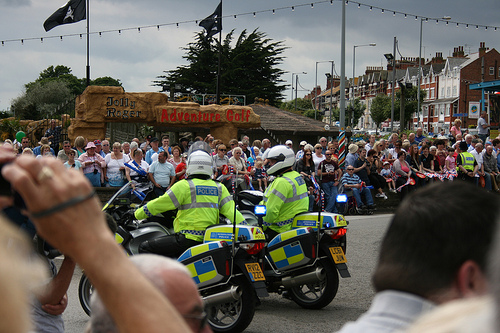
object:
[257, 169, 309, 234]
jacket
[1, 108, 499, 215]
spectators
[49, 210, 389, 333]
street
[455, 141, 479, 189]
man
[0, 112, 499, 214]
crowd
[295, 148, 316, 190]
woman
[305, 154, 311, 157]
sunglasses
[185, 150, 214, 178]
helmet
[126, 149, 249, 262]
man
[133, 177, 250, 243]
coat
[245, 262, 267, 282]
license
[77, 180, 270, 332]
bike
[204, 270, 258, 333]
wheel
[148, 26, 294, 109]
pines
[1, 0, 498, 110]
sky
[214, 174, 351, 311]
bikes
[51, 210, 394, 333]
concrete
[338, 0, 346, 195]
pole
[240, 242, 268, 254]
stop sign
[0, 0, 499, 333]
picture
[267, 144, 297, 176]
head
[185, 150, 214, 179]
head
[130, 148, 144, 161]
head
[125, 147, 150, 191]
person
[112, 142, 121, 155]
head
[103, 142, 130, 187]
person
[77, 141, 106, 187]
person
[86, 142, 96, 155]
head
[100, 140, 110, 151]
head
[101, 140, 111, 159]
person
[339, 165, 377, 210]
person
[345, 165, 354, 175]
head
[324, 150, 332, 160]
head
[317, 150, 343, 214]
person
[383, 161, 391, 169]
head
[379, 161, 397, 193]
person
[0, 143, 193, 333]
person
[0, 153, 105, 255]
hand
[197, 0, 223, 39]
flag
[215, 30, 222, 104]
pole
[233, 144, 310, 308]
motorcyclist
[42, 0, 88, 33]
flag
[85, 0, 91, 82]
pole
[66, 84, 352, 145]
store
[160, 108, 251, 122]
sign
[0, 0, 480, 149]
background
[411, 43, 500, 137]
house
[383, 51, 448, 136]
house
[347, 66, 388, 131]
house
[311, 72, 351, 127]
house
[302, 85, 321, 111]
house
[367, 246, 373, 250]
bad sentence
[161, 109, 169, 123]
letter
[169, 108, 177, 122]
letter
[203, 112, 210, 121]
letter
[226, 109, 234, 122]
letter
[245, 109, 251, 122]
letter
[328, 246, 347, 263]
license plate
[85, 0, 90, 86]
flag pole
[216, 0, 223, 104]
flag pole